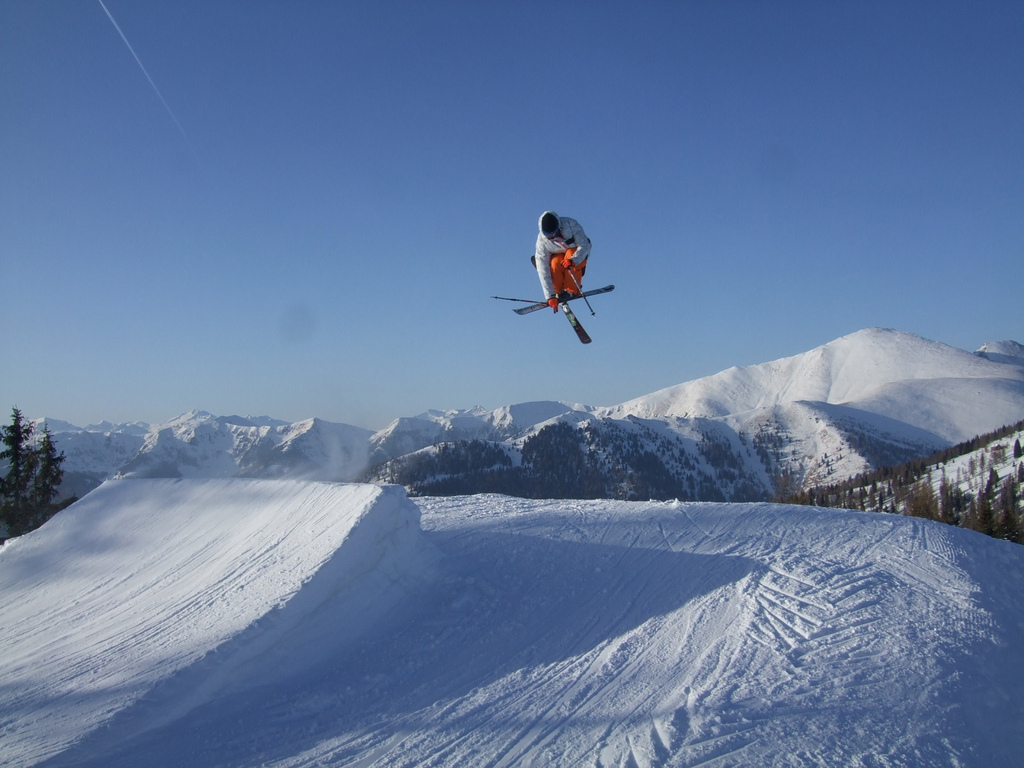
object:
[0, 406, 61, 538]
tree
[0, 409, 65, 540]
woods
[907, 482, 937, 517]
tree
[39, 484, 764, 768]
shadow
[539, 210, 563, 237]
hood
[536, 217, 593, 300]
sweater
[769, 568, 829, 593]
tracks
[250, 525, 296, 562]
tracks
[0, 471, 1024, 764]
ground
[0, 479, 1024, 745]
snow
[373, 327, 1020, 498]
mountain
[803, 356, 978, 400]
snow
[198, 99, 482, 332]
air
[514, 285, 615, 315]
skis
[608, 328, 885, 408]
hillside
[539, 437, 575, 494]
trees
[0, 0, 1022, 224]
sky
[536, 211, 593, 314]
man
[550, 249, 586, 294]
pants